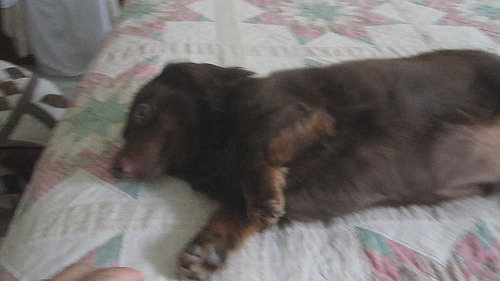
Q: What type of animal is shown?
A: Dog.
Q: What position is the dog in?
A: Laying down.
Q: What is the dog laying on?
A: Bed.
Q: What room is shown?
A: Bedroom.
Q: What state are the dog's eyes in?
A: Open.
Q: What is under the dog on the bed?
A: Bedspread.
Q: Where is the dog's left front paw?
A: Raised above the bed.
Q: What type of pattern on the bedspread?
A: Star.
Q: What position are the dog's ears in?
A: Laying down.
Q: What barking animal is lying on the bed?
A: Dog.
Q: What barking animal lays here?
A: Dog.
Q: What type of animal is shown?
A: Dog.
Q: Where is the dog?
A: Laying on bed.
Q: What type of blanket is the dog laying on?
A: Quilt.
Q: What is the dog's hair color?
A: Brown.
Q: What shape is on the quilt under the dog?
A: Star.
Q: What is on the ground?
A: A quilt.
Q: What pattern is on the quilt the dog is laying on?
A: Stars.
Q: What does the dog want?
A: To sleep on bed.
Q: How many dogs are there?
A: One.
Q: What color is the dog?
A: Brown.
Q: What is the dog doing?
A: Laying down.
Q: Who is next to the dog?
A: Noone.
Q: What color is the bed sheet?
A: White, Pink , and Blue.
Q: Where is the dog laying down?
A: On the bed.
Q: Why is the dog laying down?
A: He is resting.